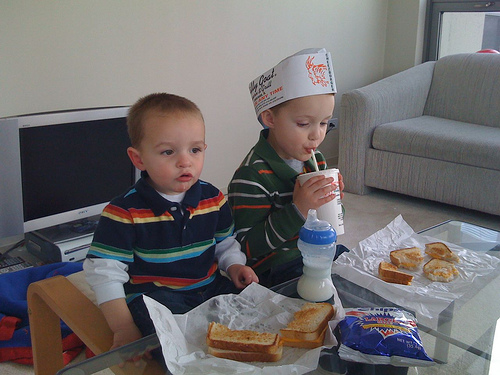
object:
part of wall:
[2, 1, 411, 221]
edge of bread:
[422, 240, 464, 261]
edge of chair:
[334, 50, 496, 216]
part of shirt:
[80, 180, 250, 296]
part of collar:
[140, 184, 204, 218]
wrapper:
[329, 214, 498, 319]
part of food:
[280, 299, 334, 347]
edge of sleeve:
[225, 165, 299, 263]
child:
[83, 91, 259, 367]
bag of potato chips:
[329, 304, 431, 366]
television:
[1, 102, 144, 244]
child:
[226, 43, 348, 311]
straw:
[306, 146, 323, 173]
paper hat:
[245, 45, 338, 129]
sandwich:
[203, 320, 281, 362]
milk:
[297, 263, 333, 300]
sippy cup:
[296, 207, 336, 304]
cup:
[296, 164, 351, 234]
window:
[426, 8, 496, 63]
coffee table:
[58, 220, 498, 372]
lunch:
[421, 257, 457, 285]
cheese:
[377, 264, 412, 281]